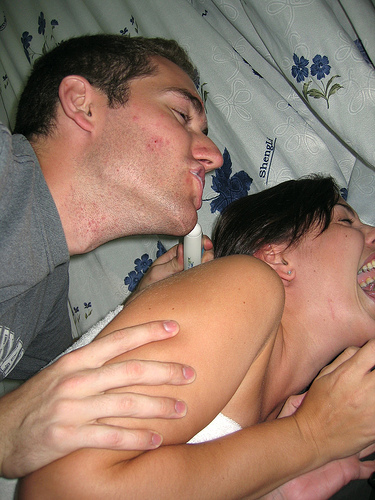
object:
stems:
[309, 75, 325, 93]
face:
[307, 196, 374, 337]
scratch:
[329, 299, 336, 321]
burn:
[70, 193, 117, 236]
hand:
[137, 234, 214, 293]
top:
[186, 412, 243, 445]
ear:
[251, 238, 295, 281]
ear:
[59, 75, 94, 133]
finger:
[78, 320, 179, 368]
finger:
[86, 392, 188, 419]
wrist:
[283, 411, 328, 478]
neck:
[282, 300, 319, 396]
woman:
[13, 173, 375, 500]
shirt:
[0, 122, 73, 385]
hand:
[0, 320, 196, 481]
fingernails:
[150, 320, 196, 448]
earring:
[288, 271, 292, 275]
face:
[132, 60, 225, 236]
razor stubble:
[66, 108, 201, 252]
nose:
[192, 130, 224, 173]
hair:
[210, 172, 347, 259]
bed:
[0, 0, 375, 499]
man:
[0, 33, 223, 479]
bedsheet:
[0, 0, 375, 500]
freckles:
[214, 276, 257, 309]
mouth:
[357, 251, 375, 302]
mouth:
[189, 166, 205, 210]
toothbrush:
[184, 223, 203, 271]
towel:
[37, 303, 242, 445]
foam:
[196, 166, 205, 188]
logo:
[0, 325, 26, 378]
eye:
[169, 106, 193, 123]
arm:
[13, 253, 312, 500]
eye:
[338, 218, 355, 225]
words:
[255, 133, 280, 183]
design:
[273, 88, 321, 155]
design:
[291, 52, 343, 108]